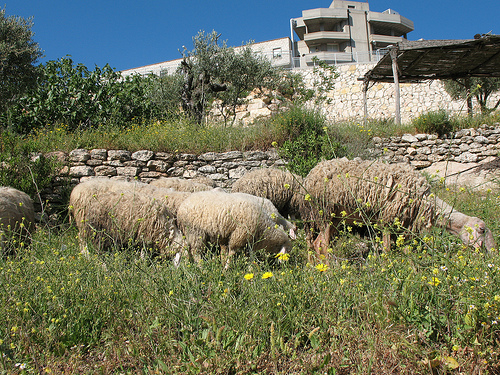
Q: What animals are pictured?
A: Sheep.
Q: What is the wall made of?
A: Stone.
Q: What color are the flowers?
A: Yellow.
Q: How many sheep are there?
A: 5.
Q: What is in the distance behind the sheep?
A: A building.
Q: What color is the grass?
A: Green.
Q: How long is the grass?
A: Very long.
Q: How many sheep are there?
A: Five.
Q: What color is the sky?
A: Blue.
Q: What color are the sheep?
A: White.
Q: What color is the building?
A: White.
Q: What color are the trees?
A: Green.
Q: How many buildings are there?
A: One.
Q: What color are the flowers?
A: Yellow.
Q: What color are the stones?
A: Gray.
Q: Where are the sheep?
A: Grass field.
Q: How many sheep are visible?
A: 6.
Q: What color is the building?
A: Grey.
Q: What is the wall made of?
A: Stones.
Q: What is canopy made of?
A: Wood.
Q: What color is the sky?
A: Blue.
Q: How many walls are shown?
A: 2.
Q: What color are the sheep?
A: White.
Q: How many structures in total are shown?
A: 2.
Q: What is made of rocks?
A: The wall.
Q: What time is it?
A: Afternoon.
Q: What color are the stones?
A: Gray.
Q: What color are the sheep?
A: White.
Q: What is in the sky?
A: Nothing.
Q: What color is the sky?
A: Blue.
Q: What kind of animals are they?
A: Sheep.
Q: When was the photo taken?
A: Afternoon.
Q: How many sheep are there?
A: Six.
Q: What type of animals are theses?
A: Sheep.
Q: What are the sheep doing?
A: Eating.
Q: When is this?
A: Daytime.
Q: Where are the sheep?
A: A field.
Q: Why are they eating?
A: Hungry.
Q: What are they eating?
A: Grass.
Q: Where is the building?
A: On the hill.